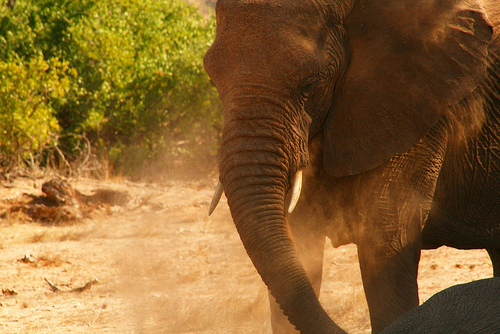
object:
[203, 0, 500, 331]
elephant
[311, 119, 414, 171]
skin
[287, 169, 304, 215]
tusk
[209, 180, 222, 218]
tusk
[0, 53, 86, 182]
bush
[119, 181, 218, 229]
sand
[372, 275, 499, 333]
elephant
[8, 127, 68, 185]
branches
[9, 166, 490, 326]
ground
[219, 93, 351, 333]
trunk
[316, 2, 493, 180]
ear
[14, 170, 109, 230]
dirt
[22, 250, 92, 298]
clump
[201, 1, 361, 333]
head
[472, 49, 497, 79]
lines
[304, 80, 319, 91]
eye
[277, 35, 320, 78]
bumps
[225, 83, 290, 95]
line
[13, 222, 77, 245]
grass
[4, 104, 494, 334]
outdoors